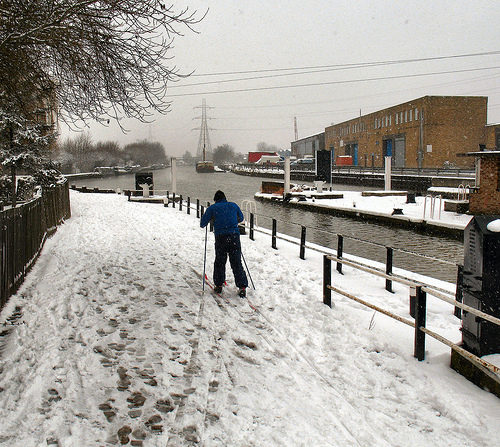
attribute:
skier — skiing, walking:
[199, 189, 258, 300]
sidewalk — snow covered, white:
[2, 182, 497, 446]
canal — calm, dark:
[68, 149, 465, 287]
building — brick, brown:
[322, 94, 486, 175]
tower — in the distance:
[187, 91, 221, 164]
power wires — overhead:
[123, 50, 500, 102]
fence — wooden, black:
[0, 175, 73, 301]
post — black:
[413, 284, 426, 362]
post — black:
[322, 252, 333, 310]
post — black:
[383, 244, 394, 295]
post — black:
[453, 262, 464, 320]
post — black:
[336, 233, 344, 275]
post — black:
[298, 224, 307, 260]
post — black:
[272, 216, 278, 252]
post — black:
[248, 211, 256, 242]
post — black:
[195, 197, 201, 220]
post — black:
[186, 195, 191, 216]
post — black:
[178, 192, 184, 213]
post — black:
[172, 189, 176, 209]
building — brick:
[459, 148, 499, 214]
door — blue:
[350, 142, 360, 166]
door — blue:
[382, 136, 394, 172]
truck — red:
[246, 149, 278, 164]